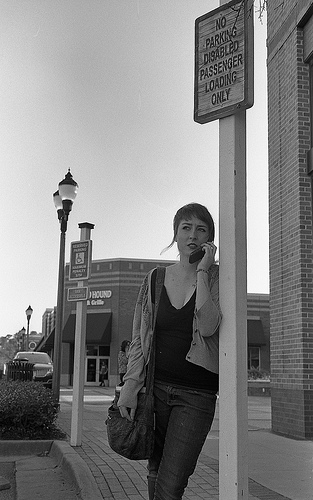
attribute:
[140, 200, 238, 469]
woman — close, staring, looking, watching, standing, talking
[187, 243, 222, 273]
phone — small, black, close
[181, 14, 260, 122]
sign — wooden, white, brown, above, high, wood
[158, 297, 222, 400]
shirt — black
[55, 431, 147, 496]
sidewalk — brick, red